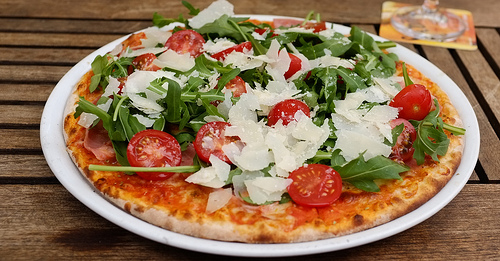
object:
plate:
[39, 13, 481, 259]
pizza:
[62, 17, 466, 245]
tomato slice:
[127, 130, 182, 180]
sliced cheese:
[79, 24, 403, 214]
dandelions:
[73, 1, 466, 194]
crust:
[62, 18, 466, 245]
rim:
[41, 14, 481, 258]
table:
[1, 1, 500, 261]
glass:
[391, 2, 467, 43]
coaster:
[378, 1, 478, 54]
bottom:
[390, 10, 469, 42]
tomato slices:
[387, 84, 432, 121]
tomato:
[287, 164, 344, 208]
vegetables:
[194, 121, 247, 163]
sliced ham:
[84, 116, 198, 177]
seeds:
[295, 175, 303, 181]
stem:
[88, 164, 200, 173]